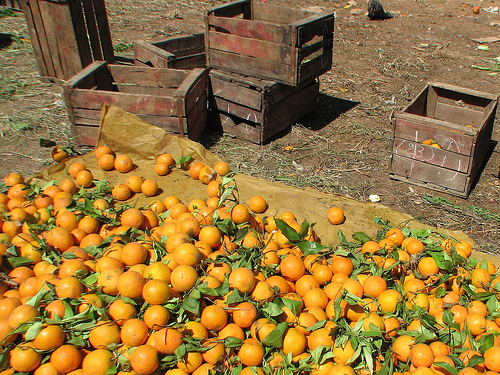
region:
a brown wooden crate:
[388, 80, 498, 200]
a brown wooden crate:
[203, 0, 336, 86]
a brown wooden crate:
[205, 66, 324, 145]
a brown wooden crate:
[58, 57, 205, 150]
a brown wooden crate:
[132, 34, 204, 66]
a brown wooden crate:
[17, 0, 114, 86]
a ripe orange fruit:
[140, 180, 157, 197]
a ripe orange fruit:
[124, 172, 142, 193]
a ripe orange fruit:
[114, 151, 130, 173]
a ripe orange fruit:
[94, 152, 112, 169]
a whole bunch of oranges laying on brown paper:
[0, 142, 496, 372]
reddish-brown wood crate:
[385, 80, 495, 196]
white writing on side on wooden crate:
[395, 126, 460, 176]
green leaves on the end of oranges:
[5, 276, 131, 346]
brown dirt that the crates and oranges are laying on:
[0, 0, 497, 255]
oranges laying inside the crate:
[418, 122, 473, 150]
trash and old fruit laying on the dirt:
[282, 0, 498, 202]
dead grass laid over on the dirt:
[0, 0, 498, 253]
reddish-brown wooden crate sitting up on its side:
[17, 0, 116, 83]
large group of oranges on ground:
[0, 139, 496, 373]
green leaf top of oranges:
[190, 282, 229, 310]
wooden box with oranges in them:
[386, 63, 499, 197]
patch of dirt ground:
[356, 23, 449, 65]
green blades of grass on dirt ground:
[258, 145, 360, 185]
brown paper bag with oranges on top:
[3, 100, 493, 374]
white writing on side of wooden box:
[396, 125, 464, 191]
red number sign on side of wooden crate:
[208, 13, 285, 79]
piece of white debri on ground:
[365, 185, 387, 205]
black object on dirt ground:
[359, 0, 399, 26]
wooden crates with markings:
[62, 54, 245, 151]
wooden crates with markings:
[367, 47, 496, 223]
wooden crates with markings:
[189, 7, 336, 92]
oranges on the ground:
[39, 175, 285, 362]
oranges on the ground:
[286, 220, 438, 330]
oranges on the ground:
[233, 193, 389, 333]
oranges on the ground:
[123, 255, 220, 350]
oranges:
[301, 274, 335, 319]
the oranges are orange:
[297, 263, 338, 314]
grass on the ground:
[318, 134, 367, 180]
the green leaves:
[219, 328, 242, 349]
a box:
[394, 113, 479, 195]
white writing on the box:
[385, 128, 471, 184]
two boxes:
[198, 18, 273, 133]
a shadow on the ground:
[305, 96, 353, 131]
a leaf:
[272, 218, 297, 240]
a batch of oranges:
[97, 245, 192, 292]